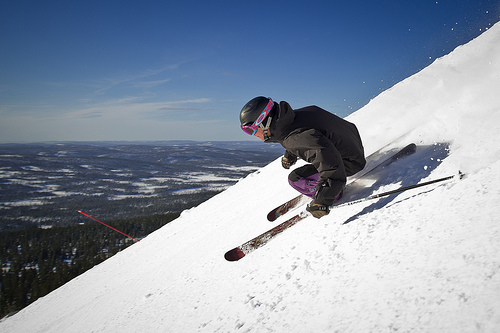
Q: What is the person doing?
A: Skiing.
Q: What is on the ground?
A: Snow.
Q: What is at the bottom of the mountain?
A: Trees.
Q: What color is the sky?
A: Blue.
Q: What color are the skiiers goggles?
A: Purple.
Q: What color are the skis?
A: Black.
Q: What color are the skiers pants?
A: Black and purple.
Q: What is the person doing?
A: Skiing.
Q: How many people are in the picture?
A: 1.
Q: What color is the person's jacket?
A: Black.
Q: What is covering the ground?
A: Snow.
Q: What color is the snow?
A: White.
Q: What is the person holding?
A: Poles.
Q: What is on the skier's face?
A: Goggles.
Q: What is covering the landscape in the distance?
A: Trees.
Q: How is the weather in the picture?
A: Sunny and clear.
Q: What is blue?
A: Sky.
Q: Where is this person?
A: Ski slope.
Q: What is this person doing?
A: Skiing.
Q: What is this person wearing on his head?
A: Helmet.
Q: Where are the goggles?
A: Around the helmet.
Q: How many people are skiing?
A: One.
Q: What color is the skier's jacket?
A: Black.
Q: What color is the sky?
A: Blue.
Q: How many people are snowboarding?
A: None.